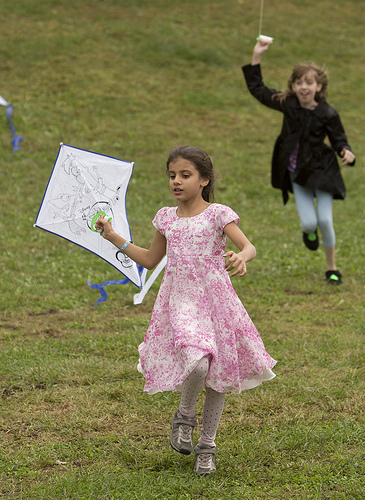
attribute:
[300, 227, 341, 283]
shoes — black 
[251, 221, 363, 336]
grass — Green 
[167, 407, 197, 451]
tennis shoes — grey , Pink 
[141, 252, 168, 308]
streamer — white 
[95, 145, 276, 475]
girl — little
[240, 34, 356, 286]
girl — young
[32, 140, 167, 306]
kite — white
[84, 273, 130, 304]
kite tail — blue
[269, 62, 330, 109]
hair — long, brown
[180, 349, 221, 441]
tights — polka-dots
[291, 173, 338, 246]
leggings — blue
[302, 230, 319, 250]
tennis shoe — black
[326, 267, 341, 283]
tennis shoe — black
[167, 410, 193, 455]
shoe — girl's , gray , of tennis 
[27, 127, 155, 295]
kite — blue and white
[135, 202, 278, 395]
dress — pink, white, pink and white,  girl's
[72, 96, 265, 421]
girl — young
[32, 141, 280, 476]
girl kite — young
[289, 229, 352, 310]
shoe — green, black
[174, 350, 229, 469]
socks — polka dotted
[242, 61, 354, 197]
coat — black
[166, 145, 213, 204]
hair — long, girl's 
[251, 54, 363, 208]
top —  girl's,  black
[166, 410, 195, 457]
shoe — gray, white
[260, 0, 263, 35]
kite string — white, kite's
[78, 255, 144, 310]
streamer — Blue 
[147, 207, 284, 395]
dress — pink